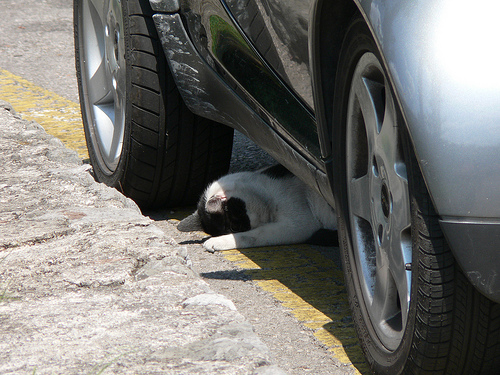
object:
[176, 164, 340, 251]
adult cat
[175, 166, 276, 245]
head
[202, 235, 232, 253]
paw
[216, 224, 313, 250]
leg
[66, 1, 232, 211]
back tire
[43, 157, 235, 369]
curb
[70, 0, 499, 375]
car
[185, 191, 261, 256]
cat sun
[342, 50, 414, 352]
rim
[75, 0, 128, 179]
rim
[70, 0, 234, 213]
tires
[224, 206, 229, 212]
eye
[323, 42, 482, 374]
tire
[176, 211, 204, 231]
ear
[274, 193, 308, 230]
white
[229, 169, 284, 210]
neck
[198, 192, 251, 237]
face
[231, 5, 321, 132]
seat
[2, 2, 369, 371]
road